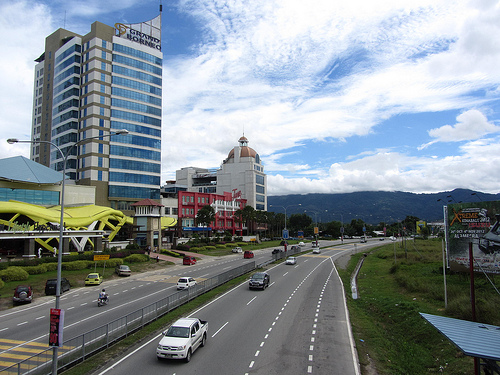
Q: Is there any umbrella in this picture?
A: No, there are no umbrellas.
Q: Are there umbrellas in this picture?
A: No, there are no umbrellas.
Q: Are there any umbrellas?
A: No, there are no umbrellas.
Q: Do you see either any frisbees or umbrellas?
A: No, there are no umbrellas or frisbees.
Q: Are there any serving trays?
A: No, there are no serving trays.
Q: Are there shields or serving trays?
A: No, there are no serving trays or shields.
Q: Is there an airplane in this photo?
A: No, there are no airplanes.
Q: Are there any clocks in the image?
A: No, there are no clocks.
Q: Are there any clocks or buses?
A: No, there are no clocks or buses.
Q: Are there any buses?
A: No, there are no buses.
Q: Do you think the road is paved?
A: Yes, the road is paved.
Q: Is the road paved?
A: Yes, the road is paved.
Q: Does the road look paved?
A: Yes, the road is paved.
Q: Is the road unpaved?
A: No, the road is paved.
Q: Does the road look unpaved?
A: No, the road is paved.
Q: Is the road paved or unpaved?
A: The road is paved.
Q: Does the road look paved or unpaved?
A: The road is paved.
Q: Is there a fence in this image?
A: Yes, there is a fence.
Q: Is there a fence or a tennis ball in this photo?
A: Yes, there is a fence.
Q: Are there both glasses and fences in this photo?
A: No, there is a fence but no glasses.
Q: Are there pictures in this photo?
A: No, there are no pictures.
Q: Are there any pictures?
A: No, there are no pictures.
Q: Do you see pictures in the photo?
A: No, there are no pictures.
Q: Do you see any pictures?
A: No, there are no pictures.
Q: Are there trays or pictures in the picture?
A: No, there are no pictures or trays.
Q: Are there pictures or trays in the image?
A: No, there are no pictures or trays.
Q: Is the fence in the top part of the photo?
A: No, the fence is in the bottom of the image.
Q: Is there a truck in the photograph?
A: Yes, there is a truck.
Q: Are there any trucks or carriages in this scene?
A: Yes, there is a truck.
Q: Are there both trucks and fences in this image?
A: Yes, there are both a truck and a fence.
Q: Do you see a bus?
A: No, there are no buses.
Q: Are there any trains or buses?
A: No, there are no buses or trains.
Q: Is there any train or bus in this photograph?
A: No, there are no buses or trains.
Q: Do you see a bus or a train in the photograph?
A: No, there are no buses or trains.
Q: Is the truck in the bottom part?
A: Yes, the truck is in the bottom of the image.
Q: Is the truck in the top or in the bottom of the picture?
A: The truck is in the bottom of the image.